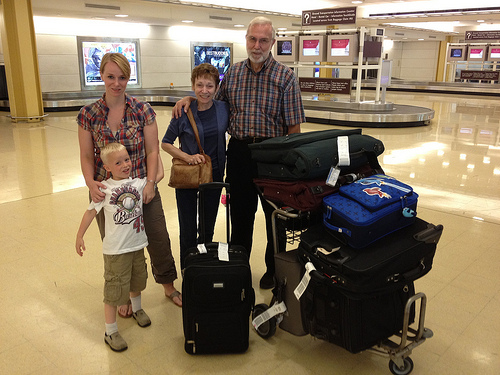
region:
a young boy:
[60, 137, 168, 357]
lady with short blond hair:
[72, 38, 192, 322]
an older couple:
[162, 9, 308, 304]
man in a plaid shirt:
[221, 15, 298, 305]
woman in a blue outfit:
[165, 57, 228, 317]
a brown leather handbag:
[159, 91, 215, 203]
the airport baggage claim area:
[24, 14, 477, 368]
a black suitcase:
[177, 173, 258, 370]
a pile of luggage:
[247, 128, 443, 355]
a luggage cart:
[263, 199, 450, 372]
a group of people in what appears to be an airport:
[5, 3, 495, 372]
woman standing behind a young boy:
[70, 48, 172, 360]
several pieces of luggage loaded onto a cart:
[253, 118, 439, 373]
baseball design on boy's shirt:
[73, 140, 163, 256]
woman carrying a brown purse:
[162, 57, 237, 197]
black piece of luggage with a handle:
[170, 163, 266, 360]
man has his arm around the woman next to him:
[161, 13, 307, 188]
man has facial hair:
[234, 13, 281, 75]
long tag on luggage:
[250, 236, 338, 338]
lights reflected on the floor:
[387, 83, 498, 205]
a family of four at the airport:
[61, 14, 386, 359]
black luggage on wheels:
[180, 183, 258, 356]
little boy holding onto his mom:
[61, 58, 178, 358]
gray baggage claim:
[20, 73, 426, 135]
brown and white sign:
[299, 6, 359, 31]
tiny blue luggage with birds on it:
[321, 168, 423, 245]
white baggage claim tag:
[290, 261, 320, 302]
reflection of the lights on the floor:
[410, 143, 499, 185]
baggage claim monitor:
[448, 45, 464, 57]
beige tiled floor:
[5, 122, 499, 362]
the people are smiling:
[57, 10, 296, 230]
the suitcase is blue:
[323, 163, 442, 237]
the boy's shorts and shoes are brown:
[101, 253, 149, 366]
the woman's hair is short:
[189, 55, 233, 106]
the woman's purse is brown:
[163, 147, 225, 197]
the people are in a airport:
[0, 2, 487, 362]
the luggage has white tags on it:
[176, 133, 453, 331]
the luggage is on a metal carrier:
[257, 126, 445, 369]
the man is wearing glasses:
[238, 25, 278, 52]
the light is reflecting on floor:
[387, 130, 498, 215]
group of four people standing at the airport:
[47, 16, 442, 370]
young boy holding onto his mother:
[59, 51, 178, 363]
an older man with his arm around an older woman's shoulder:
[155, 15, 315, 303]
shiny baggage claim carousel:
[40, 76, 432, 129]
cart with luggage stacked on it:
[251, 138, 439, 374]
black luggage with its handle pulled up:
[175, 174, 260, 355]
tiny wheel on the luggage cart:
[385, 355, 415, 374]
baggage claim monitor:
[448, 44, 465, 61]